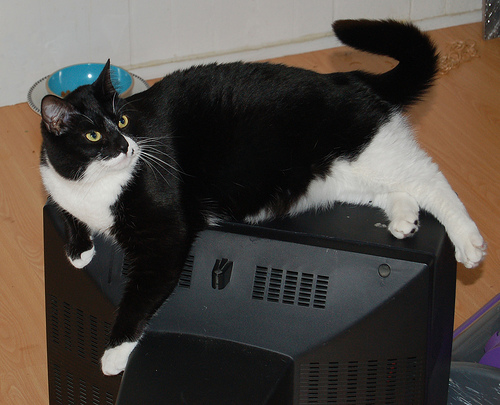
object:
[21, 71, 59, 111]
saucer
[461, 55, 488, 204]
table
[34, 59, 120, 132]
ears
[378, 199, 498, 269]
back paws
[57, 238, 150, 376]
front paws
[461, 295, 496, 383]
clothing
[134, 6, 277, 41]
wall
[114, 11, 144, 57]
crack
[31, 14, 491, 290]
cat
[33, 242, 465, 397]
television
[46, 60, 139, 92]
bowl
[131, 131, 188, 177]
whiskers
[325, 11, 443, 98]
tail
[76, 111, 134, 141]
eyes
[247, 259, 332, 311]
vents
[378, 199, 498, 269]
paws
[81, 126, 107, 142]
eye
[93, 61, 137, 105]
ear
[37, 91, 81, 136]
ear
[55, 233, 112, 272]
paw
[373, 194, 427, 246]
paw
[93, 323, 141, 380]
paw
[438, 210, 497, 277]
paw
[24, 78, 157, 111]
plate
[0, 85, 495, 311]
floor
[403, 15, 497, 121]
section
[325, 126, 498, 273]
legs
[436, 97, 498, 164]
wood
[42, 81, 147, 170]
head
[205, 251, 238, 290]
mount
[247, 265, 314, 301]
cooling